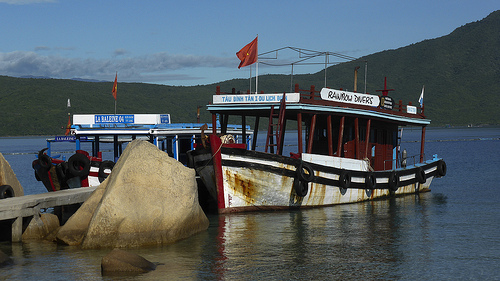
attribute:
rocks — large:
[3, 134, 215, 278]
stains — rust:
[222, 160, 439, 203]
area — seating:
[61, 140, 129, 168]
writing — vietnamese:
[95, 112, 129, 124]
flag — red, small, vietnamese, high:
[234, 40, 259, 69]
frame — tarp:
[252, 47, 366, 98]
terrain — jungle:
[2, 11, 500, 132]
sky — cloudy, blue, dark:
[1, 1, 499, 86]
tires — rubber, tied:
[29, 148, 98, 184]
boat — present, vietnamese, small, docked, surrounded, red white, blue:
[191, 36, 451, 214]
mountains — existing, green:
[1, 8, 499, 138]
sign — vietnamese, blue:
[212, 92, 295, 104]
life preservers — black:
[287, 159, 431, 203]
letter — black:
[327, 87, 337, 101]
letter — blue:
[219, 95, 228, 103]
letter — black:
[353, 95, 359, 103]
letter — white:
[100, 115, 105, 124]